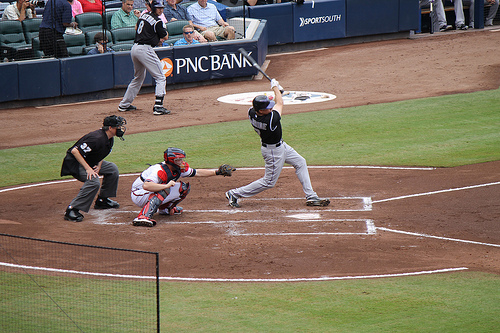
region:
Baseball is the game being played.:
[15, 0, 494, 329]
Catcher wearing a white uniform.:
[119, 112, 245, 239]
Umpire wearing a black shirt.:
[57, 89, 127, 224]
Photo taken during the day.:
[7, 12, 491, 325]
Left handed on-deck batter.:
[120, 0, 197, 122]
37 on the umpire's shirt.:
[72, 134, 90, 165]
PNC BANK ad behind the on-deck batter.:
[155, 52, 272, 80]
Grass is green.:
[0, 84, 492, 331]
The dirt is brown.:
[7, 165, 499, 275]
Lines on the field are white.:
[0, 149, 492, 290]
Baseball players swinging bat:
[223, 93, 331, 209]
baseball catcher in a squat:
[128, 146, 234, 224]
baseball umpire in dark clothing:
[59, 112, 126, 222]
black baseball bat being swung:
[236, 46, 286, 98]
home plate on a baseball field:
[288, 208, 321, 220]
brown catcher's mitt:
[211, 162, 237, 180]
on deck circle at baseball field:
[218, 87, 338, 106]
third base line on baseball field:
[372, 179, 498, 206]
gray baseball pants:
[230, 143, 318, 199]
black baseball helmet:
[248, 93, 276, 109]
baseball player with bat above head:
[215, 35, 345, 240]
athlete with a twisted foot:
[245, 80, 336, 217]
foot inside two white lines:
[261, 146, 348, 216]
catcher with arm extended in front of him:
[126, 135, 236, 230]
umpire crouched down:
[40, 95, 125, 225]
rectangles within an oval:
[2, 146, 452, 311]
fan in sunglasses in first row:
[166, 20, 211, 55]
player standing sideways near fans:
[105, 0, 207, 120]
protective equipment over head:
[82, 110, 134, 140]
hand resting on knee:
[72, 163, 103, 193]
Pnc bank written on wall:
[165, 38, 275, 90]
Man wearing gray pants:
[251, 117, 326, 216]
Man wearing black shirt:
[246, 100, 278, 146]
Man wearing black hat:
[236, 90, 281, 124]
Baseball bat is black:
[235, 45, 311, 126]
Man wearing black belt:
[252, 110, 289, 174]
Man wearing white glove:
[261, 77, 300, 109]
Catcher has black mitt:
[208, 164, 232, 192]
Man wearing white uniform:
[136, 168, 180, 209]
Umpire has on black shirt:
[60, 120, 120, 200]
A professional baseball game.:
[1, 1, 498, 331]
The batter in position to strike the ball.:
[226, 47, 330, 211]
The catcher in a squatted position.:
[130, 138, 237, 225]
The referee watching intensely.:
[61, 96, 126, 220]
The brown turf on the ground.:
[200, 208, 499, 268]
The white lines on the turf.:
[276, 208, 499, 245]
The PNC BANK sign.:
[162, 47, 260, 79]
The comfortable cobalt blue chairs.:
[1, 21, 29, 60]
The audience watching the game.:
[169, 3, 252, 42]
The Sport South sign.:
[294, 7, 351, 27]